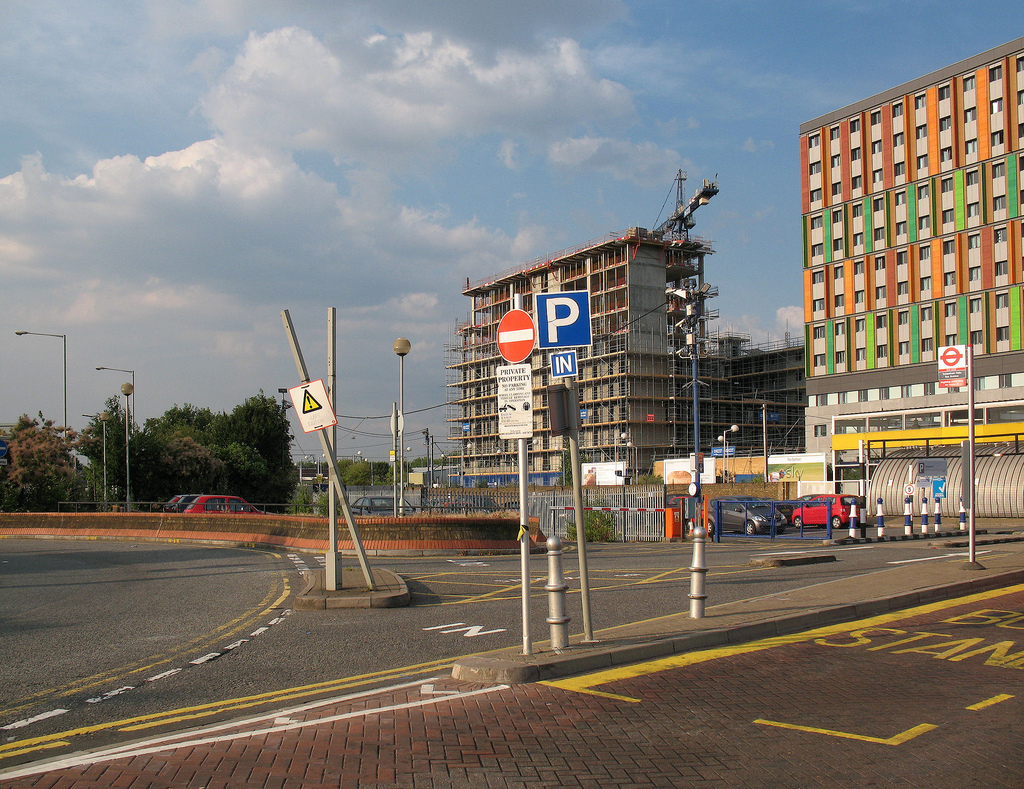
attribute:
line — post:
[713, 494, 979, 534]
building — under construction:
[431, 223, 804, 519]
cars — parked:
[720, 465, 863, 530]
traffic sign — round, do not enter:
[491, 304, 537, 363]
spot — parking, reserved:
[458, 507, 987, 786]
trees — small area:
[16, 399, 314, 507]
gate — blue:
[711, 491, 845, 542]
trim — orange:
[876, 93, 902, 193]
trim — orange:
[967, 66, 996, 168]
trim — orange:
[836, 114, 856, 205]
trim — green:
[900, 187, 920, 250]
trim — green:
[950, 168, 966, 240]